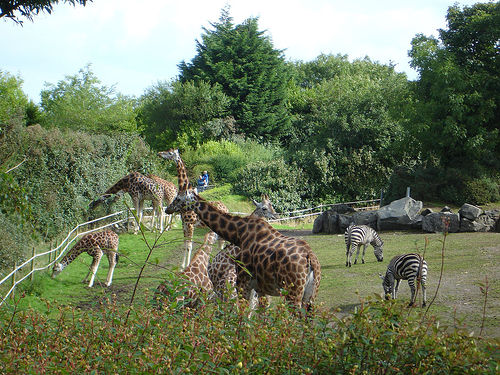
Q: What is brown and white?
A: Giraffe.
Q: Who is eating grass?
A: Zebra.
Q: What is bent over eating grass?
A: Giraffe.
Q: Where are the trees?
A: Behind the fence.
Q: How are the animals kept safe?
A: Fence.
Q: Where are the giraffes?
A: In the grass.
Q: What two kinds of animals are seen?
A: Zebra and giraffe.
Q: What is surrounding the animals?
A: Fence.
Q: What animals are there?
A: Giraffes and zebras?.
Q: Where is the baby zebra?
A: By the fence.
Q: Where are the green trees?
A: Behind the rocks.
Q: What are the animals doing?
A: Eating a lot of food.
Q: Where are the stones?
A: In a line by the zebras.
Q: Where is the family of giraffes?
A: Along the fence looking or eating.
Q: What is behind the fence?
A: A hedge.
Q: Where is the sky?
A: Above the animals.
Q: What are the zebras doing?
A: Eating.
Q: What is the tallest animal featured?
A: The giraffe.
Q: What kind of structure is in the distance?
A: Stone.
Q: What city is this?
A: Cleveland.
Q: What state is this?
A: Ohio.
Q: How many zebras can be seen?
A: Two.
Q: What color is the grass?
A: Green.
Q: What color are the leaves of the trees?
A: Green.